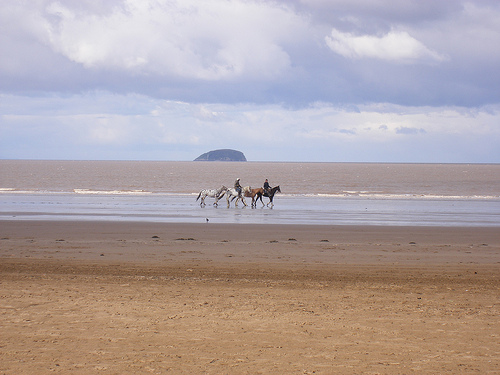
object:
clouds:
[29, 0, 307, 78]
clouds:
[323, 26, 445, 68]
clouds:
[250, 102, 452, 135]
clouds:
[49, 102, 158, 144]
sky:
[1, 1, 499, 163]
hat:
[235, 173, 243, 183]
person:
[233, 176, 243, 197]